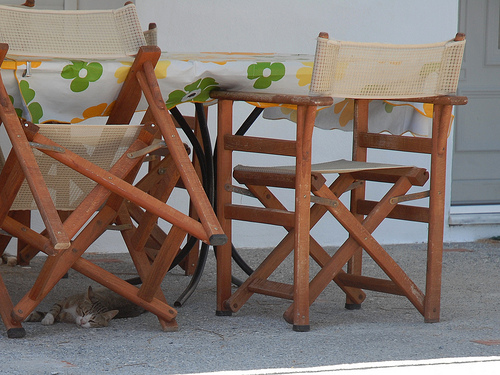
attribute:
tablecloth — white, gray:
[2, 52, 454, 126]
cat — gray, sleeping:
[25, 276, 150, 329]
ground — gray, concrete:
[3, 239, 500, 374]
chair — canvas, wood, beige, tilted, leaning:
[2, 3, 225, 336]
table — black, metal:
[1, 54, 453, 309]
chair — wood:
[220, 33, 468, 330]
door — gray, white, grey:
[452, 2, 499, 206]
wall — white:
[2, 2, 456, 254]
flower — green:
[246, 61, 285, 90]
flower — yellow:
[70, 103, 115, 123]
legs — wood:
[214, 221, 443, 332]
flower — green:
[167, 78, 220, 107]